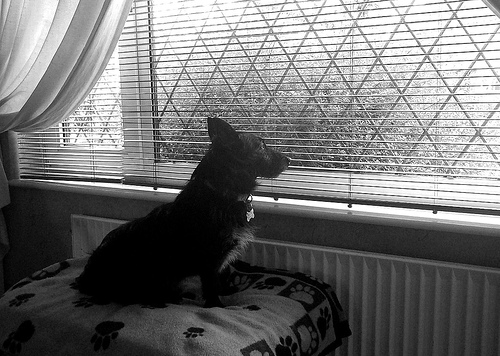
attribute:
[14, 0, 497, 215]
blinds — white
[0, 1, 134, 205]
curtain — white